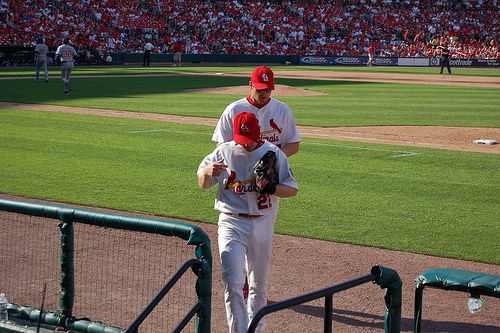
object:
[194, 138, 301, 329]
uniform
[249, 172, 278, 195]
hand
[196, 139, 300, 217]
jersey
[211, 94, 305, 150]
jersey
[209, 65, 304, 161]
man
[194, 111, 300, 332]
man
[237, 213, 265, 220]
belt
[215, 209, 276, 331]
pants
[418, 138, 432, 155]
ground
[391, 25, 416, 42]
people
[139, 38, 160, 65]
people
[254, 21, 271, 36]
people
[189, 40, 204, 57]
people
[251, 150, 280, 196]
glove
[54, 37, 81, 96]
man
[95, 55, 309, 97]
fence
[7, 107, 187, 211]
grass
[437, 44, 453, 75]
umpire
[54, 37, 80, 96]
player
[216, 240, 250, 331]
leg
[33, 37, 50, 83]
player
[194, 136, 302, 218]
shirt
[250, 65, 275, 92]
cap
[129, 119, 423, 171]
train track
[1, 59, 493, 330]
field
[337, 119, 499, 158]
base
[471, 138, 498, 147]
base plate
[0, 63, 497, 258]
baseball field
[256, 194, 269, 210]
red 21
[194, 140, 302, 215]
white jersey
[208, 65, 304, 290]
baseball player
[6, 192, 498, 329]
dugout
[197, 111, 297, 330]
baseball player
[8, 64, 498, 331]
baseball field